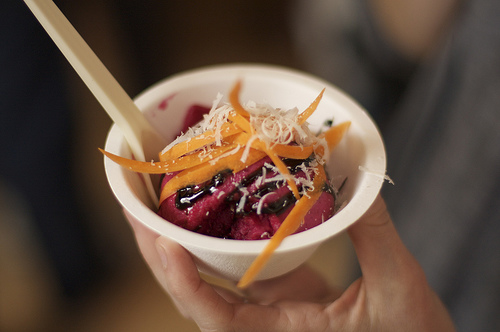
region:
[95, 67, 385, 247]
a small bowl full of food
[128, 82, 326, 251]
some sliced carrots on top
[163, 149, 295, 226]
some sliced meat under the carrots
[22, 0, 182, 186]
a utensil laying on the side of the bowl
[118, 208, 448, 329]
the hand holding the bowl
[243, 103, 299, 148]
shredded cheese on top of the food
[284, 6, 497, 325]
the person standing by the bowl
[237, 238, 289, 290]
a piece of carrot hanging over the bowl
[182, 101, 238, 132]
some more shredded cheese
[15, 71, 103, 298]
another person standing around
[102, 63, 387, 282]
Ivory colored plastic fruit bowl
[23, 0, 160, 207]
A plastic ivory colored spoon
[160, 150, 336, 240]
Strawberries chopped into slices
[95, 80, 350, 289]
Thin carrot strips laid on the strawberries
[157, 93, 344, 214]
Grated cheese on top of the carrot strips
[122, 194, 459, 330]
Hand holding the fruit bowl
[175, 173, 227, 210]
jam on the strawberries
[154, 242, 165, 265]
Nail on one finger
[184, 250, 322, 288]
Rough surface on the outside of the bowl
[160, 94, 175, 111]
Jam stain on the inside of the bowl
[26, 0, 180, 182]
Plastic utensil in cup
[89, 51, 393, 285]
White cup with dessert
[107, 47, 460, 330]
White hand holding white cup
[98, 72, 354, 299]
Orange pieces of fruit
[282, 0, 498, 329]
Gray shirt in the background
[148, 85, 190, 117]
Piece of red food on side of the cup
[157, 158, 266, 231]
Purple food in white cup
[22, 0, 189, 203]
White plastic spoon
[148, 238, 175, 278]
Person has clear nails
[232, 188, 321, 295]
Orange piece of food hanging over cup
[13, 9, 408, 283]
disposable bowl with spoon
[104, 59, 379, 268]
coconut sprinkled on frozen dessert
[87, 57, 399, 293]
shreds of fruit on ice cream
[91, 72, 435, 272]
purple ice cream in bowl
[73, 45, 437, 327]
hand holding small bowl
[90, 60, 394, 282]
dark sauce on ice cream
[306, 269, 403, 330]
creases on hand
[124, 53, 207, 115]
ice cream smeared on side of cup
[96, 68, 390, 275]
frozen dessert in cup held in hand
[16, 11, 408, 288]
spoon in bowl with ice cream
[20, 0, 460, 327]
hand holding sundae with a spoon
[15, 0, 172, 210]
white plastic spoon in a sundae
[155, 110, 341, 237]
raspberry looking sherbet in a sundae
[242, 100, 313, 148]
white coconut shreds on a sundae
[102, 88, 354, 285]
orange mango shredded on a sundae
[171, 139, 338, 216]
fruit sauce on top of sherbet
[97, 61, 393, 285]
small white plastic cup holding sundae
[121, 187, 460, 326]
hand holding a small fruit sundae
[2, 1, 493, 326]
blurry background of a person in the photo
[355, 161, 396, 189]
bit of coconut shred hanging over edge of bowl